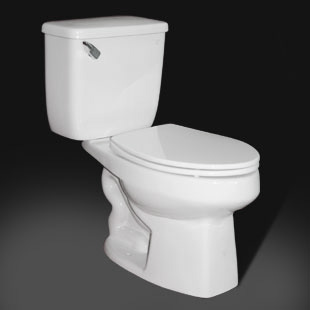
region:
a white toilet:
[40, 18, 262, 298]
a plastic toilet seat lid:
[110, 121, 260, 168]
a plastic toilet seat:
[110, 138, 261, 175]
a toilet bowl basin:
[80, 140, 263, 298]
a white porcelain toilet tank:
[41, 34, 165, 139]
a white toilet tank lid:
[41, 14, 169, 37]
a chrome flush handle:
[81, 39, 101, 59]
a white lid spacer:
[195, 168, 202, 171]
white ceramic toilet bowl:
[40, 7, 280, 306]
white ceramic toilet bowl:
[44, 7, 270, 306]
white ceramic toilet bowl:
[35, 8, 264, 307]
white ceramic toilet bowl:
[29, 4, 270, 306]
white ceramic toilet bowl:
[39, 19, 278, 309]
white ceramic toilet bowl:
[35, 12, 250, 299]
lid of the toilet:
[125, 120, 250, 168]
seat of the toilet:
[130, 162, 239, 178]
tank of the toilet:
[41, 20, 164, 36]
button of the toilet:
[66, 37, 100, 56]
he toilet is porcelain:
[163, 192, 209, 214]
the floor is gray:
[17, 222, 70, 260]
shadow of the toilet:
[243, 213, 293, 272]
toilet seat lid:
[113, 114, 261, 167]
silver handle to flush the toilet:
[80, 39, 102, 62]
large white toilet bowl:
[92, 119, 266, 217]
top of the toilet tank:
[39, 8, 165, 44]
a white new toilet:
[47, 10, 262, 296]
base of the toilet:
[97, 202, 250, 295]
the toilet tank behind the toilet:
[38, 5, 174, 146]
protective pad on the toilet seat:
[190, 172, 203, 180]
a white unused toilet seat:
[110, 116, 264, 178]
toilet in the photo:
[14, 15, 285, 230]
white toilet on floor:
[122, 125, 276, 189]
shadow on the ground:
[250, 185, 305, 249]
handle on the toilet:
[66, 28, 120, 73]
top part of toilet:
[47, 6, 176, 52]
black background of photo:
[199, 11, 298, 76]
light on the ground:
[26, 243, 91, 298]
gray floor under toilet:
[37, 238, 97, 284]